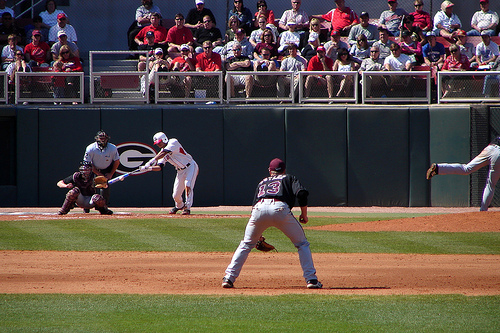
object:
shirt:
[403, 11, 434, 31]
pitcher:
[220, 157, 325, 290]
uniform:
[219, 174, 320, 282]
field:
[0, 206, 500, 333]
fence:
[0, 71, 499, 104]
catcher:
[55, 161, 114, 215]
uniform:
[156, 138, 200, 210]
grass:
[2, 212, 499, 256]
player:
[139, 131, 202, 217]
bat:
[107, 166, 148, 185]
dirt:
[1, 251, 499, 295]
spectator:
[357, 45, 388, 104]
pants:
[172, 160, 200, 210]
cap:
[266, 158, 288, 172]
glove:
[253, 235, 278, 253]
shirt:
[248, 173, 309, 209]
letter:
[268, 176, 273, 181]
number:
[268, 181, 281, 196]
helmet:
[151, 131, 169, 146]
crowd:
[2, 1, 497, 96]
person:
[191, 40, 224, 104]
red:
[195, 51, 224, 77]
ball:
[118, 175, 125, 180]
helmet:
[78, 160, 94, 179]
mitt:
[93, 175, 111, 189]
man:
[425, 136, 500, 213]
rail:
[12, 72, 86, 106]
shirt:
[23, 42, 50, 62]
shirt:
[194, 52, 221, 71]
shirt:
[304, 55, 333, 71]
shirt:
[164, 24, 193, 45]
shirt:
[321, 8, 359, 35]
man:
[24, 29, 51, 62]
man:
[164, 13, 193, 54]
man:
[310, 0, 361, 36]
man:
[301, 44, 334, 104]